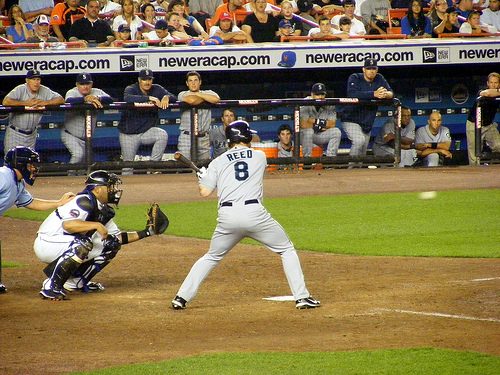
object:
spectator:
[166, 13, 196, 44]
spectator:
[399, 0, 431, 33]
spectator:
[431, 10, 462, 33]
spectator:
[457, 10, 497, 37]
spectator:
[265, 0, 302, 29]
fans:
[3, 1, 498, 44]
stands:
[4, 9, 494, 82]